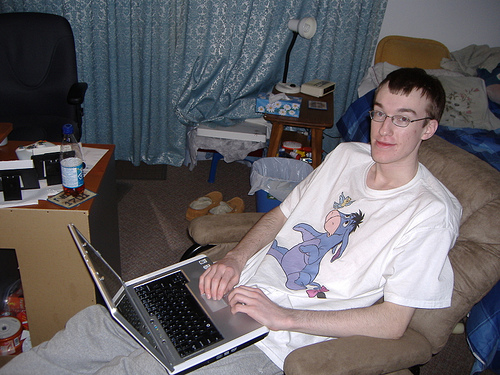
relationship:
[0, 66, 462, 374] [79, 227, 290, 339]
man using laptop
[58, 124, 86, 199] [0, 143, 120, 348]
bottle on table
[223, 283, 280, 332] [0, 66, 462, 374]
left hand of man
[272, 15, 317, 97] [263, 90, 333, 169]
lamp on desk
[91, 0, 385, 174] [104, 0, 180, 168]
curtain on window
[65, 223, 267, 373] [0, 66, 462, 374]
laptop on man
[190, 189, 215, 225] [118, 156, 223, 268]
shoe on floor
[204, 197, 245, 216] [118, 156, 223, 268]
shoes on floor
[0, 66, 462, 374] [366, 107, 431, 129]
man wearing spectacles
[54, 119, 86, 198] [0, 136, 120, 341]
bottle on table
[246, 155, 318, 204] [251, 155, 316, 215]
trash bag in garbage can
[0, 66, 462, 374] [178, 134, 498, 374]
man in chair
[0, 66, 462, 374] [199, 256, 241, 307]
man has hand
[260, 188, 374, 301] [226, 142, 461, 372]
cartoon on t shirt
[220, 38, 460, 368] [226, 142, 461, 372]
man wearing t shirt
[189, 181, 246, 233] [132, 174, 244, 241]
shoes on carpet